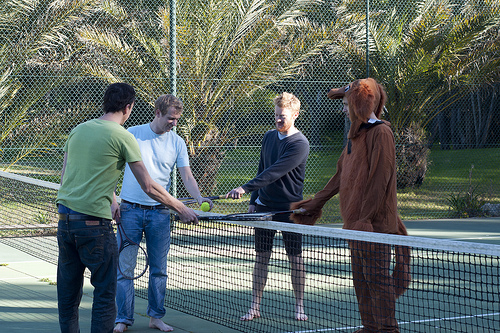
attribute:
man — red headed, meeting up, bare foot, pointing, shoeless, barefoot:
[227, 92, 308, 321]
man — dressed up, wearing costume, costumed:
[289, 78, 411, 333]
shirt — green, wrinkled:
[54, 119, 141, 222]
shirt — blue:
[120, 123, 190, 207]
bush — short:
[73, 0, 335, 197]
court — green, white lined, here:
[0, 217, 499, 332]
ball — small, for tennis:
[200, 201, 211, 211]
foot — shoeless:
[240, 307, 260, 323]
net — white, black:
[0, 172, 499, 333]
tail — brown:
[394, 219, 409, 298]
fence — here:
[0, 0, 499, 237]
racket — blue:
[200, 212, 273, 221]